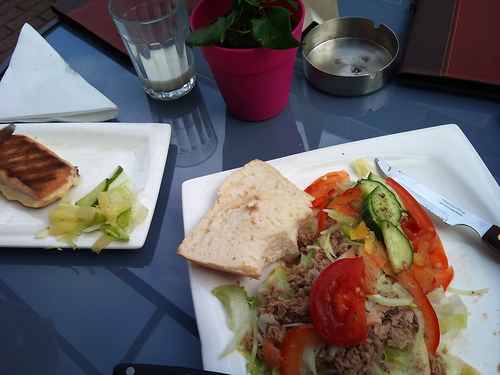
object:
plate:
[181, 124, 498, 373]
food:
[310, 257, 365, 346]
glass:
[106, 0, 198, 100]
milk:
[132, 44, 195, 92]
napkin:
[0, 23, 120, 122]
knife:
[373, 158, 499, 251]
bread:
[177, 157, 316, 280]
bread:
[0, 132, 80, 209]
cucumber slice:
[378, 219, 415, 274]